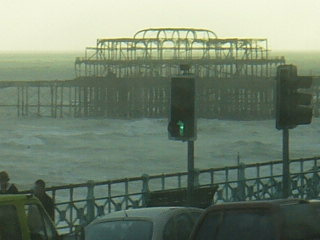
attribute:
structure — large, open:
[67, 32, 285, 94]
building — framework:
[72, 32, 258, 87]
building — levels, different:
[67, 25, 266, 118]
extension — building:
[9, 55, 73, 113]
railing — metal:
[46, 164, 286, 216]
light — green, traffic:
[169, 75, 193, 143]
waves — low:
[15, 125, 123, 146]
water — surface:
[7, 116, 167, 160]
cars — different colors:
[96, 214, 313, 234]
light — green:
[177, 121, 185, 133]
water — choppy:
[0, 50, 319, 236]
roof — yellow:
[0, 191, 40, 206]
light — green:
[171, 120, 185, 138]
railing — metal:
[0, 153, 318, 239]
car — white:
[66, 203, 209, 239]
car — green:
[0, 190, 61, 239]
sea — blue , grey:
[5, 115, 308, 170]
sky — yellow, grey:
[4, 3, 319, 47]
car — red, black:
[193, 195, 316, 238]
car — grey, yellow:
[84, 201, 202, 238]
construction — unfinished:
[71, 24, 286, 127]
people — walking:
[4, 165, 59, 220]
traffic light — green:
[162, 70, 202, 147]